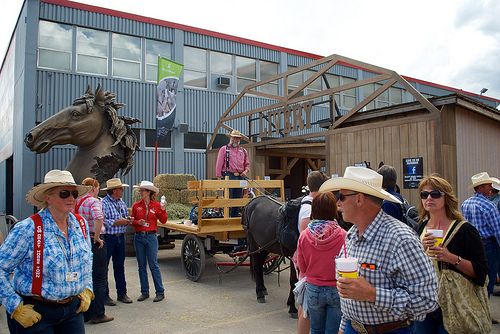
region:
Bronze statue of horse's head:
[22, 83, 139, 177]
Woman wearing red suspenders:
[25, 165, 93, 295]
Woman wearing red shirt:
[133, 179, 161, 229]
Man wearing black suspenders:
[213, 125, 250, 175]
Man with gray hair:
[222, 122, 252, 153]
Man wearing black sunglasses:
[335, 166, 385, 228]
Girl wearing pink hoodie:
[295, 188, 342, 287]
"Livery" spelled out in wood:
[255, 98, 319, 141]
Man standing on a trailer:
[213, 124, 244, 228]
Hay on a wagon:
[164, 168, 199, 223]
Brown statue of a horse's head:
[23, 85, 140, 192]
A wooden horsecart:
[154, 173, 284, 278]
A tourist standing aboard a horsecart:
[215, 129, 250, 216]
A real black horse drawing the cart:
[244, 195, 297, 317]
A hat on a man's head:
[319, 165, 401, 202]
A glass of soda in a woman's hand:
[425, 230, 442, 258]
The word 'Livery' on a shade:
[259, 99, 312, 138]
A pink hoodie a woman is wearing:
[296, 219, 346, 284]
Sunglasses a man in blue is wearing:
[59, 189, 79, 198]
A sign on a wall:
[402, 158, 423, 188]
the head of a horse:
[29, 76, 136, 201]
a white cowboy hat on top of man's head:
[313, 162, 405, 212]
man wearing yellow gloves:
[6, 286, 101, 327]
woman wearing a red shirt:
[129, 198, 168, 233]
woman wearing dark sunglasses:
[49, 189, 78, 201]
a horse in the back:
[245, 189, 307, 323]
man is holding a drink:
[335, 235, 360, 298]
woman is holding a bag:
[436, 213, 496, 332]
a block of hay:
[150, 171, 197, 189]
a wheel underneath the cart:
[177, 230, 208, 281]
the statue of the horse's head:
[23, 82, 143, 198]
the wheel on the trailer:
[180, 232, 205, 278]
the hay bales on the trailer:
[131, 172, 212, 218]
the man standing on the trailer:
[215, 129, 250, 218]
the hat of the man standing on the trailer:
[224, 129, 246, 139]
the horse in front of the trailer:
[238, 194, 298, 318]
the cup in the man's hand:
[334, 236, 358, 278]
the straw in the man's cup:
[340, 236, 347, 259]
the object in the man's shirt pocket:
[360, 262, 377, 270]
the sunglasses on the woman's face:
[417, 188, 444, 200]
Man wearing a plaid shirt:
[321, 165, 435, 332]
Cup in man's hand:
[334, 231, 360, 298]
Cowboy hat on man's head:
[318, 159, 400, 213]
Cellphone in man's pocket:
[357, 253, 384, 280]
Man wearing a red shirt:
[210, 128, 252, 218]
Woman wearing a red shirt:
[129, 180, 180, 302]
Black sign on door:
[396, 148, 426, 195]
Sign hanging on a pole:
[149, 47, 184, 154]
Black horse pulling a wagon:
[154, 168, 314, 315]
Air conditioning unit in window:
[209, 72, 237, 93]